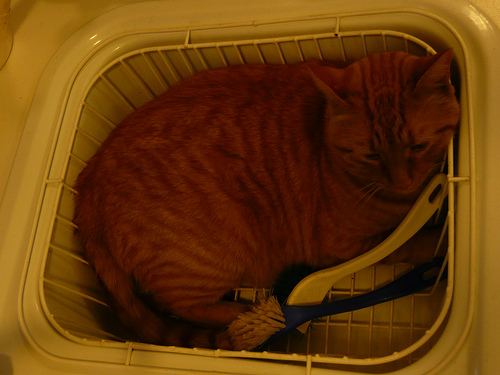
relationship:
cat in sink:
[67, 43, 464, 351] [4, 1, 499, 374]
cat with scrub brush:
[67, 43, 464, 351] [217, 254, 452, 352]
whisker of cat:
[350, 181, 385, 209] [67, 43, 464, 351]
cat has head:
[67, 43, 464, 351] [305, 46, 461, 195]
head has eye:
[305, 46, 461, 195] [353, 147, 382, 166]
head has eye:
[305, 46, 461, 195] [403, 138, 429, 155]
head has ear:
[305, 46, 461, 195] [303, 61, 352, 106]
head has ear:
[305, 46, 461, 195] [416, 48, 453, 90]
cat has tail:
[67, 43, 464, 351] [79, 231, 237, 348]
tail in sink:
[79, 231, 237, 348] [4, 1, 499, 374]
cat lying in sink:
[67, 43, 464, 351] [4, 1, 499, 374]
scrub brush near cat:
[217, 254, 452, 352] [67, 43, 464, 351]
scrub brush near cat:
[266, 171, 440, 331] [67, 43, 464, 351]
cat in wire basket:
[67, 43, 464, 351] [34, 28, 458, 364]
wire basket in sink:
[34, 28, 458, 364] [4, 1, 499, 374]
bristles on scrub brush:
[226, 297, 288, 348] [217, 254, 452, 352]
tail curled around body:
[79, 231, 237, 348] [92, 58, 341, 298]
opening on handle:
[424, 183, 443, 205] [371, 169, 451, 267]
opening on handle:
[416, 264, 440, 279] [317, 251, 450, 314]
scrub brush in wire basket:
[217, 254, 452, 352] [34, 28, 458, 364]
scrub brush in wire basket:
[266, 171, 440, 331] [34, 28, 458, 364]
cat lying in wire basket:
[67, 43, 464, 351] [34, 28, 458, 364]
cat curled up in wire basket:
[67, 43, 464, 351] [34, 28, 458, 364]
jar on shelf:
[1, 5, 20, 77] [0, 3, 37, 374]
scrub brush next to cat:
[217, 254, 452, 352] [67, 43, 464, 351]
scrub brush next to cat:
[266, 171, 440, 331] [67, 43, 464, 351]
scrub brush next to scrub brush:
[266, 171, 440, 331] [217, 254, 452, 352]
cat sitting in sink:
[67, 43, 464, 351] [4, 1, 499, 374]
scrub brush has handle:
[266, 171, 440, 331] [371, 169, 451, 267]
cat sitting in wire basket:
[67, 43, 464, 351] [34, 28, 458, 364]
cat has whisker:
[67, 43, 464, 351] [350, 181, 385, 209]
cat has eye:
[67, 43, 464, 351] [353, 147, 382, 166]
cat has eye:
[67, 43, 464, 351] [403, 138, 429, 155]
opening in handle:
[424, 183, 443, 205] [371, 169, 451, 267]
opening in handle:
[416, 264, 440, 279] [317, 251, 450, 314]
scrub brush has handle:
[217, 254, 452, 352] [317, 251, 450, 314]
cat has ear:
[67, 43, 464, 351] [303, 61, 352, 106]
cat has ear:
[67, 43, 464, 351] [416, 48, 453, 90]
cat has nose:
[67, 43, 464, 351] [379, 171, 413, 194]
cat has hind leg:
[67, 43, 464, 351] [126, 242, 258, 331]